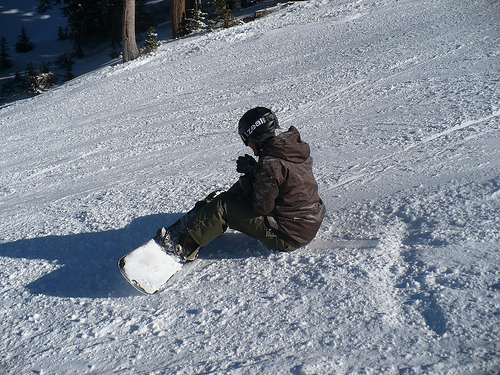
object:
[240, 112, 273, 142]
strap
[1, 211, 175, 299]
shadow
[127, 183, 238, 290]
snow board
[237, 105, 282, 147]
helmet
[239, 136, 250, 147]
goggles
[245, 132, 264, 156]
face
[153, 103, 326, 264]
woman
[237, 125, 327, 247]
brown coat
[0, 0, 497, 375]
snow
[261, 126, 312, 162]
hood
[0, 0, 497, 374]
hill side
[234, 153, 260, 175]
glove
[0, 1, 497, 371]
slope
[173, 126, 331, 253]
snow suit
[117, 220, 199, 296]
feet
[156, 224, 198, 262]
boot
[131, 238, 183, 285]
snow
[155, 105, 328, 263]
man